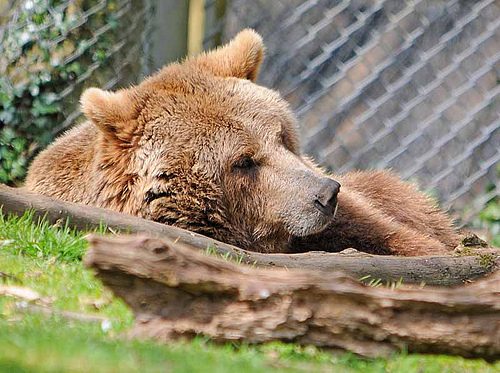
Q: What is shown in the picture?
A: A grassy area.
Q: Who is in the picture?
A: A bear.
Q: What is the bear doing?
A: Laying down.